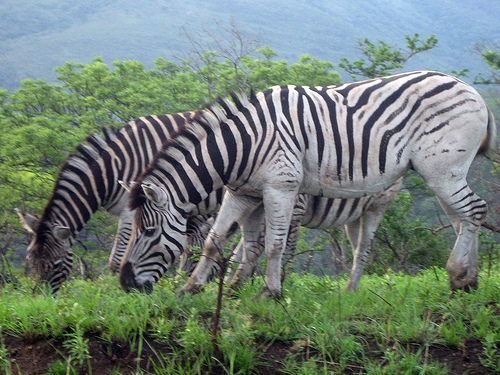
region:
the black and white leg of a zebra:
[109, 208, 134, 275]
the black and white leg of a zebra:
[184, 188, 255, 292]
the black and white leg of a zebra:
[228, 213, 265, 295]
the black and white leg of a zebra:
[262, 166, 292, 299]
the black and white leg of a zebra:
[277, 195, 306, 292]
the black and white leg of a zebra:
[346, 216, 363, 286]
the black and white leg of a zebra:
[346, 194, 392, 291]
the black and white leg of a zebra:
[417, 126, 487, 288]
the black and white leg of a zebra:
[431, 173, 483, 295]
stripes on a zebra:
[221, 100, 328, 156]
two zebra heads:
[11, 147, 205, 290]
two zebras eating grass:
[13, 66, 497, 316]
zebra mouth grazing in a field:
[110, 255, 173, 304]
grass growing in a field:
[255, 295, 318, 363]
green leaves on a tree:
[92, 65, 157, 102]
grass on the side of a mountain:
[103, 23, 180, 46]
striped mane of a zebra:
[65, 132, 102, 164]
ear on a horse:
[9, 198, 43, 243]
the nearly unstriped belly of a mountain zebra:
[272, 152, 428, 215]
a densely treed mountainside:
[0, 2, 496, 94]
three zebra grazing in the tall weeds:
[15, 171, 180, 301]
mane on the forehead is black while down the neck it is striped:
[117, 92, 257, 208]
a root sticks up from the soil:
[180, 227, 260, 344]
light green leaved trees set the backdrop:
[0, 28, 498, 263]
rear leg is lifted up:
[426, 165, 487, 306]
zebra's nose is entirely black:
[118, 255, 148, 295]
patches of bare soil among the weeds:
[0, 336, 452, 373]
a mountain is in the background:
[10, 6, 493, 65]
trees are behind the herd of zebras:
[2, 36, 490, 176]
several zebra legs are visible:
[108, 200, 483, 301]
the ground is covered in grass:
[4, 269, 494, 369]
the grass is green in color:
[9, 274, 488, 361]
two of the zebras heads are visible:
[10, 151, 190, 304]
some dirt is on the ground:
[1, 337, 65, 373]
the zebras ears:
[113, 172, 168, 209]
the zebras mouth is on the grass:
[121, 255, 164, 302]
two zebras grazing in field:
[0, 52, 487, 274]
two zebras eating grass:
[27, 77, 485, 327]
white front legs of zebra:
[183, 185, 294, 321]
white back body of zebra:
[389, 68, 495, 160]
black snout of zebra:
[108, 257, 146, 291]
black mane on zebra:
[29, 183, 52, 263]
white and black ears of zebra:
[40, 218, 79, 241]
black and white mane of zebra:
[33, 146, 70, 211]